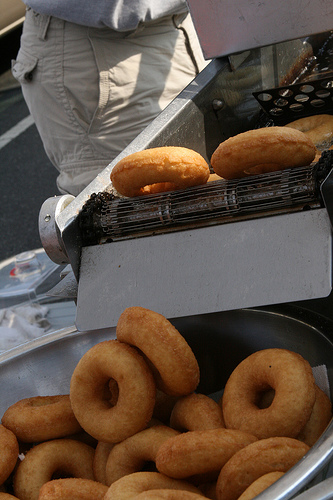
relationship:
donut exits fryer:
[108, 143, 214, 199] [35, 1, 331, 342]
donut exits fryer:
[206, 122, 318, 184] [35, 1, 331, 342]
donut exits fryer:
[112, 303, 203, 401] [35, 1, 331, 342]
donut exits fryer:
[66, 335, 161, 447] [35, 1, 331, 342]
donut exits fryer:
[220, 344, 320, 444] [35, 1, 331, 342]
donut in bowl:
[112, 303, 203, 401] [1, 304, 332, 498]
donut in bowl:
[66, 335, 161, 447] [1, 304, 332, 498]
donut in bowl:
[220, 344, 320, 444] [1, 304, 332, 498]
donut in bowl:
[152, 425, 261, 482] [1, 304, 332, 498]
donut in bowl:
[210, 434, 315, 500] [1, 304, 332, 498]